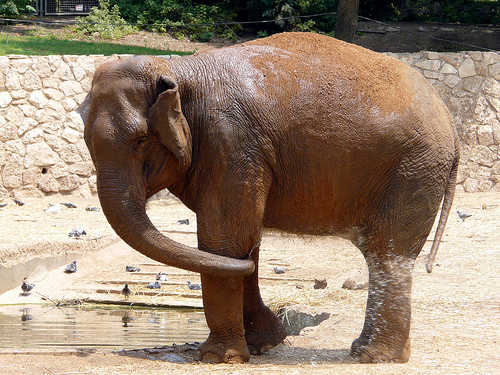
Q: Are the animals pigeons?
A: No, there are both pigeons and birds.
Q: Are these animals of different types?
A: Yes, they are pigeons and birds.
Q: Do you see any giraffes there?
A: No, there are no giraffes.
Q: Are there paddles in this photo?
A: No, there are no paddles.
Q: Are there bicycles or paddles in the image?
A: No, there are no paddles or bicycles.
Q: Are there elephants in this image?
A: Yes, there is an elephant.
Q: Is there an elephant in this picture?
A: Yes, there is an elephant.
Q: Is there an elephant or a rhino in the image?
A: Yes, there is an elephant.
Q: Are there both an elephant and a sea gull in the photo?
A: No, there is an elephant but no seagulls.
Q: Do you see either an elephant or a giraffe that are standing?
A: Yes, the elephant is standing.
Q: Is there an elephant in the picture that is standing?
A: Yes, there is an elephant that is standing.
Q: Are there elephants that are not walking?
A: Yes, there is an elephant that is standing.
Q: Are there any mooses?
A: No, there are no mooses.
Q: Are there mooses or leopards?
A: No, there are no mooses or leopards.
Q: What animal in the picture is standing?
A: The animal is an elephant.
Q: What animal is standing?
A: The animal is an elephant.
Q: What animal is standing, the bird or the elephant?
A: The elephant is standing.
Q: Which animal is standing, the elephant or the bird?
A: The elephant is standing.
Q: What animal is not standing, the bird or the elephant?
A: The bird is not standing.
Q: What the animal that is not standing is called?
A: The animal is a bird.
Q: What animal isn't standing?
A: The animal is a bird.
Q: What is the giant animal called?
A: The animal is an elephant.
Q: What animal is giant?
A: The animal is an elephant.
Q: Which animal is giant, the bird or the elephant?
A: The elephant is giant.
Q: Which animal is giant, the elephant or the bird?
A: The elephant is giant.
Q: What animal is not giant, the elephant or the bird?
A: The bird is not giant.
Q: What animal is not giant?
A: The animal is a bird.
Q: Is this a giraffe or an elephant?
A: This is an elephant.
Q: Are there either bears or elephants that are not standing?
A: No, there is an elephant but it is standing.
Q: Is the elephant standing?
A: Yes, the elephant is standing.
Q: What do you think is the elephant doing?
A: The elephant is standing.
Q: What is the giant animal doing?
A: The elephant is standing.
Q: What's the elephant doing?
A: The elephant is standing.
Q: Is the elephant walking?
A: No, the elephant is standing.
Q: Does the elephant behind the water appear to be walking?
A: No, the elephant is standing.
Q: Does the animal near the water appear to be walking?
A: No, the elephant is standing.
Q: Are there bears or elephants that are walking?
A: No, there is an elephant but it is standing.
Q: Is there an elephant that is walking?
A: No, there is an elephant but it is standing.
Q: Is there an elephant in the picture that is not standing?
A: No, there is an elephant but it is standing.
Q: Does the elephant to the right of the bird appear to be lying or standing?
A: The elephant is standing.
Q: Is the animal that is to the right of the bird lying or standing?
A: The elephant is standing.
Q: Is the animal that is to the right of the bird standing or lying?
A: The elephant is standing.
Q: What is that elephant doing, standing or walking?
A: The elephant is standing.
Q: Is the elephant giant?
A: Yes, the elephant is giant.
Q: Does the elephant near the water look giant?
A: Yes, the elephant is giant.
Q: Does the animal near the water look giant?
A: Yes, the elephant is giant.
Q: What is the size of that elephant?
A: The elephant is giant.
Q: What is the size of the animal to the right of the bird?
A: The elephant is giant.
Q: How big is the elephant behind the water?
A: The elephant is giant.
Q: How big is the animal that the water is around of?
A: The elephant is giant.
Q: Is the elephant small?
A: No, the elephant is giant.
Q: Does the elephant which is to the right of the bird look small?
A: No, the elephant is giant.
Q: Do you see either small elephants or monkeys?
A: No, there is an elephant but it is giant.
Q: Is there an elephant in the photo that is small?
A: No, there is an elephant but it is giant.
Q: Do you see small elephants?
A: No, there is an elephant but it is giant.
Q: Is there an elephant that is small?
A: No, there is an elephant but it is giant.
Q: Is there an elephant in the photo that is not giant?
A: No, there is an elephant but it is giant.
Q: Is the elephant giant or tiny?
A: The elephant is giant.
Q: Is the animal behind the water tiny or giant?
A: The elephant is giant.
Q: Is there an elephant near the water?
A: Yes, there is an elephant near the water.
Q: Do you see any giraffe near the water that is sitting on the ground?
A: No, there is an elephant near the water.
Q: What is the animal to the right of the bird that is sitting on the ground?
A: The animal is an elephant.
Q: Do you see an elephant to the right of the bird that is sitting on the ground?
A: Yes, there is an elephant to the right of the bird.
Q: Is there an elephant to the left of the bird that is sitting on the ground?
A: No, the elephant is to the right of the bird.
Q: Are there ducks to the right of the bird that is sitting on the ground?
A: No, there is an elephant to the right of the bird.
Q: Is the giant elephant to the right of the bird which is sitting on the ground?
A: Yes, the elephant is to the right of the bird.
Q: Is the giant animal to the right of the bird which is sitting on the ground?
A: Yes, the elephant is to the right of the bird.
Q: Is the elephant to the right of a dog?
A: No, the elephant is to the right of the bird.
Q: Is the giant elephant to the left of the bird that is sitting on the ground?
A: No, the elephant is to the right of the bird.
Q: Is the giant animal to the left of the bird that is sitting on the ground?
A: No, the elephant is to the right of the bird.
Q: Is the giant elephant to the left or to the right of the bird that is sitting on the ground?
A: The elephant is to the right of the bird.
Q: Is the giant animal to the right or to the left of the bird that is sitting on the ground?
A: The elephant is to the right of the bird.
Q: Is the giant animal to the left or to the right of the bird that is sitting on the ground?
A: The elephant is to the right of the bird.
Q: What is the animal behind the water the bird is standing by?
A: The animal is an elephant.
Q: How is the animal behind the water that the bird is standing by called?
A: The animal is an elephant.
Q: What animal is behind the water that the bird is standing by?
A: The animal is an elephant.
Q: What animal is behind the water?
A: The animal is an elephant.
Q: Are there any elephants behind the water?
A: Yes, there is an elephant behind the water.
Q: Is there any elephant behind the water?
A: Yes, there is an elephant behind the water.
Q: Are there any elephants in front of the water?
A: No, the elephant is behind the water.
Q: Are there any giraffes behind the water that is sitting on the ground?
A: No, there is an elephant behind the water.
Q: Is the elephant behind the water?
A: Yes, the elephant is behind the water.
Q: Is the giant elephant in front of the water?
A: No, the elephant is behind the water.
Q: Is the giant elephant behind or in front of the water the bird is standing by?
A: The elephant is behind the water.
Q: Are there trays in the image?
A: No, there are no trays.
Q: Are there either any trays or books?
A: No, there are no trays or books.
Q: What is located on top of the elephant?
A: The dirt is on top of the elephant.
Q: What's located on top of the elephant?
A: The dirt is on top of the elephant.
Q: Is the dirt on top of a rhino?
A: No, the dirt is on top of an elephant.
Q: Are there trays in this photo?
A: No, there are no trays.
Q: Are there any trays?
A: No, there are no trays.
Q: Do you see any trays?
A: No, there are no trays.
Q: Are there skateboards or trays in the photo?
A: No, there are no trays or skateboards.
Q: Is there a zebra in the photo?
A: No, there are no zebras.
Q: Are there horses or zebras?
A: No, there are no zebras or horses.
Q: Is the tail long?
A: Yes, the tail is long.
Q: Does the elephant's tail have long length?
A: Yes, the tail is long.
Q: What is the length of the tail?
A: The tail is long.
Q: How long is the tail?
A: The tail is long.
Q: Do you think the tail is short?
A: No, the tail is long.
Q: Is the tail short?
A: No, the tail is long.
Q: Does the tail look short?
A: No, the tail is long.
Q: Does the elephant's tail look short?
A: No, the tail is long.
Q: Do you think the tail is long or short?
A: The tail is long.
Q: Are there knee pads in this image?
A: No, there are no knee pads.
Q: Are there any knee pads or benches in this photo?
A: No, there are no knee pads or benches.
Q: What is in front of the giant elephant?
A: The water is in front of the elephant.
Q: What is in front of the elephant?
A: The water is in front of the elephant.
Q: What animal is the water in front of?
A: The water is in front of the elephant.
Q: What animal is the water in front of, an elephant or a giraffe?
A: The water is in front of an elephant.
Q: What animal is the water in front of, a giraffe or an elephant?
A: The water is in front of an elephant.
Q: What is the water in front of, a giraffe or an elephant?
A: The water is in front of an elephant.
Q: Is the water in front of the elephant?
A: Yes, the water is in front of the elephant.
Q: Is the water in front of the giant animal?
A: Yes, the water is in front of the elephant.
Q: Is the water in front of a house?
A: No, the water is in front of the elephant.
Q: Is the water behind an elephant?
A: No, the water is in front of an elephant.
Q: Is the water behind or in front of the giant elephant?
A: The water is in front of the elephant.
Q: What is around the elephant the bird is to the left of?
A: The water is around the elephant.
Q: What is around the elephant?
A: The water is around the elephant.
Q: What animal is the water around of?
A: The water is around the elephant.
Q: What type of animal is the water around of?
A: The water is around the elephant.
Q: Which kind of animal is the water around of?
A: The water is around the elephant.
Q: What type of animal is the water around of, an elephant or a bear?
A: The water is around an elephant.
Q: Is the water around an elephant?
A: Yes, the water is around an elephant.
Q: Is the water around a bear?
A: No, the water is around an elephant.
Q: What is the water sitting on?
A: The water is sitting on the ground.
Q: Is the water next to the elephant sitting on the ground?
A: Yes, the water is sitting on the ground.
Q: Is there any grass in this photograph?
A: Yes, there is grass.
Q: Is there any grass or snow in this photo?
A: Yes, there is grass.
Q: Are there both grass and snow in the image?
A: No, there is grass but no snow.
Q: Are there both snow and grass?
A: No, there is grass but no snow.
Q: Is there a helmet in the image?
A: No, there are no helmets.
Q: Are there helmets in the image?
A: No, there are no helmets.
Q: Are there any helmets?
A: No, there are no helmets.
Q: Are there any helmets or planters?
A: No, there are no helmets or planters.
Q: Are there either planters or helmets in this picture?
A: No, there are no helmets or planters.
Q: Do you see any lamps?
A: No, there are no lamps.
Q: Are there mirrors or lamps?
A: No, there are no lamps or mirrors.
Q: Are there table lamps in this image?
A: No, there are no table lamps.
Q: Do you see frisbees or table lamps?
A: No, there are no table lamps or frisbees.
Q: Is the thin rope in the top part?
A: Yes, the rope is in the top of the image.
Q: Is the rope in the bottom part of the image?
A: No, the rope is in the top of the image.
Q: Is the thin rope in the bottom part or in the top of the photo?
A: The rope is in the top of the image.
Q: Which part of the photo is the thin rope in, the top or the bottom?
A: The rope is in the top of the image.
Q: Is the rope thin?
A: Yes, the rope is thin.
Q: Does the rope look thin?
A: Yes, the rope is thin.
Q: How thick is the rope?
A: The rope is thin.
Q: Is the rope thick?
A: No, the rope is thin.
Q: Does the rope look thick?
A: No, the rope is thin.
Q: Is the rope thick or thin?
A: The rope is thin.